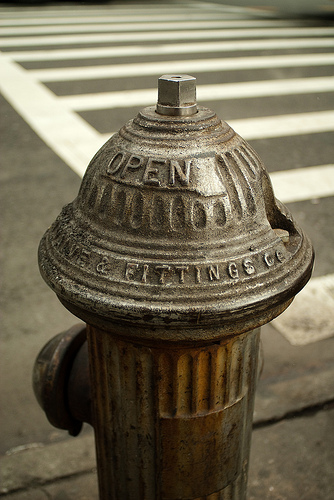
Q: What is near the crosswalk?
A: A fire hydrant.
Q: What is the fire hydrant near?
A: The street.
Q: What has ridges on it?
A: A fire hydrant.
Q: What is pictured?
A: A grey fire hydrant.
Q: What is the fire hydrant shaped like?
A: A cylinder.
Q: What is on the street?
A: White lines.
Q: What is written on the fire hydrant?
A: "OPEN".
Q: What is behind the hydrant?
A: A street.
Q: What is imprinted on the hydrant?
A: The name of the company.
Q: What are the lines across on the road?
A: Pedestrian crossing.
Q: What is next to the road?
A: A silver fire hydrant.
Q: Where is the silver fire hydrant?
A: Next to the road.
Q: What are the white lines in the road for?
A: They designate a crosswalk.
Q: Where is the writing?
A: On the top of the fire hydrant.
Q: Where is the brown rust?
A: On the bottom of the hydrant.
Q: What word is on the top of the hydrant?
A: OPEN.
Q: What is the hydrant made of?
A: Metal.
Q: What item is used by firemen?
A: Hydrant.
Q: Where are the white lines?
A: On the road.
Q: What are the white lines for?
A: Pedestrian crossing.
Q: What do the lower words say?
A: Valve & Fittings Co.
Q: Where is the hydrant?
A: On the sidewalk.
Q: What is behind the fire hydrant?
A: The street.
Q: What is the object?
A: A fire hydrant.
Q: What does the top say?
A: Open.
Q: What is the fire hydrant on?
A: The sidewalk.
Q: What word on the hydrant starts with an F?
A: Fittings.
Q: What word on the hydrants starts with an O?
A: Open.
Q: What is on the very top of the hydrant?
A: A bolt.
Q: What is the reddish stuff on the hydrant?
A: Rust.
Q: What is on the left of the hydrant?
A: The water opening.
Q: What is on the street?
A: White lines.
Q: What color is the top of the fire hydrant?
A: Silver.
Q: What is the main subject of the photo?
A: Fire hydrant.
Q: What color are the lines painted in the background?
A: White.